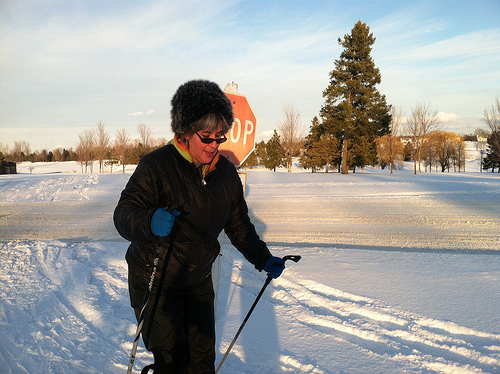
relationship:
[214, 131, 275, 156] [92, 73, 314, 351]
sunglasses on woman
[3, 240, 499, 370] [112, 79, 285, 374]
trails behind she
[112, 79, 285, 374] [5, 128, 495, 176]
she on foreground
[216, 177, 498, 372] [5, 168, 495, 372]
snow on ground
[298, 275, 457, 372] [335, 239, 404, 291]
tracks on snow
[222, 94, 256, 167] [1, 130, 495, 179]
sign on background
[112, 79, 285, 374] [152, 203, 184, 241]
she wearing glove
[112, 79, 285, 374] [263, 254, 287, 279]
she wearing glove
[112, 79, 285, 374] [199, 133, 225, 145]
she wearing sunglasses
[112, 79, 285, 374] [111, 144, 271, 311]
she wearing coat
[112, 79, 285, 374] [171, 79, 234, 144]
she has hair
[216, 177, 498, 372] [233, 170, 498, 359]
snow covering ground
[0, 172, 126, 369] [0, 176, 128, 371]
snow covering ground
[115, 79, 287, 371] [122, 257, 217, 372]
she wearing pants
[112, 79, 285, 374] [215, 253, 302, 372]
she holding pole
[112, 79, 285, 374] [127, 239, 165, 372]
she holding pole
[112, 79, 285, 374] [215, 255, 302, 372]
she riding pole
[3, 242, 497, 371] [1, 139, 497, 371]
tracks in snow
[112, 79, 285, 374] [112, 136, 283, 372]
she wearing skiing gear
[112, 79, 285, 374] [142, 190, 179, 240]
she wearing gloves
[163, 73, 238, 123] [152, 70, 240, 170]
hat on head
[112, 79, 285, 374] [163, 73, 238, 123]
she wearing hat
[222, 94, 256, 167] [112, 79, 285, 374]
sign behind she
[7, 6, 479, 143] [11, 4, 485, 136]
sky covered in clouds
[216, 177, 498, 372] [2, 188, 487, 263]
snow covering road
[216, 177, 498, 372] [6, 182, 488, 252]
snow covering street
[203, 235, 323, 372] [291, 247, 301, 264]
shade has edge